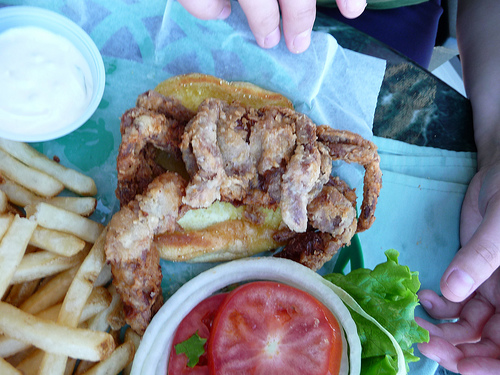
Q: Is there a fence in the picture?
A: No, there are no fences.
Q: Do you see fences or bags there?
A: No, there are no fences or bags.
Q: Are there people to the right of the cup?
A: Yes, there is a person to the right of the cup.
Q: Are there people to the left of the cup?
A: No, the person is to the right of the cup.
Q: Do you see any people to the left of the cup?
A: No, the person is to the right of the cup.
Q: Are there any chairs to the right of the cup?
A: No, there is a person to the right of the cup.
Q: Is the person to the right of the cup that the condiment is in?
A: Yes, the person is to the right of the cup.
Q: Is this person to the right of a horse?
A: No, the person is to the right of the cup.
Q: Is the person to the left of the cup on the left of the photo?
A: No, the person is to the right of the cup.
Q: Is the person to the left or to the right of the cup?
A: The person is to the right of the cup.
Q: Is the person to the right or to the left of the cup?
A: The person is to the right of the cup.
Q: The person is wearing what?
A: The person is wearing trousers.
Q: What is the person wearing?
A: The person is wearing trousers.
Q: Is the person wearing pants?
A: Yes, the person is wearing pants.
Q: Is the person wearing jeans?
A: No, the person is wearing pants.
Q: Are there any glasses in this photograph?
A: No, there are no glasses.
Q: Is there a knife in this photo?
A: No, there are no knives.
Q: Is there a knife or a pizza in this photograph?
A: No, there are no knives or pizzas.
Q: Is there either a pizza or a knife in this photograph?
A: No, there are no knives or pizzas.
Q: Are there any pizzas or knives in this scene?
A: No, there are no knives or pizzas.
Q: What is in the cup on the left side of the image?
A: The condiment is in the cup.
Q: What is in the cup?
A: The condiment is in the cup.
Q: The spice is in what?
A: The spice is in the cup.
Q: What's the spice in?
A: The spice is in the cup.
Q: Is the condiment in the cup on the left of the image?
A: Yes, the condiment is in the cup.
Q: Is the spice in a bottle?
A: No, the spice is in the cup.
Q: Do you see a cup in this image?
A: Yes, there is a cup.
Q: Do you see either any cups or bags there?
A: Yes, there is a cup.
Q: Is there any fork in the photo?
A: No, there are no forks.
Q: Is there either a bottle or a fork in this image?
A: No, there are no forks or bottles.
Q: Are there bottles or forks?
A: No, there are no forks or bottles.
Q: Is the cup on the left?
A: Yes, the cup is on the left of the image.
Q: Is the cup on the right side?
A: No, the cup is on the left of the image.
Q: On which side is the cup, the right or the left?
A: The cup is on the left of the image.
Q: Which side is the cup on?
A: The cup is on the left of the image.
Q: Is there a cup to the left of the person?
A: Yes, there is a cup to the left of the person.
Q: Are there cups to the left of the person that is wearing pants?
A: Yes, there is a cup to the left of the person.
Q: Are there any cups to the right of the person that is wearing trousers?
A: No, the cup is to the left of the person.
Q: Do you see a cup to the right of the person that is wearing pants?
A: No, the cup is to the left of the person.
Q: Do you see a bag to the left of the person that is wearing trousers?
A: No, there is a cup to the left of the person.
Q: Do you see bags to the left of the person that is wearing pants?
A: No, there is a cup to the left of the person.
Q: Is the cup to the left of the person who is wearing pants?
A: Yes, the cup is to the left of the person.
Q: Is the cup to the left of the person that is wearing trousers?
A: Yes, the cup is to the left of the person.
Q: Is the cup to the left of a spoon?
A: No, the cup is to the left of the person.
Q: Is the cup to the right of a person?
A: No, the cup is to the left of a person.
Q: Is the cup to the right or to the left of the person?
A: The cup is to the left of the person.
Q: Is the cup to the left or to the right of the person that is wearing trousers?
A: The cup is to the left of the person.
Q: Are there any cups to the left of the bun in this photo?
A: Yes, there is a cup to the left of the bun.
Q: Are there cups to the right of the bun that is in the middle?
A: No, the cup is to the left of the bun.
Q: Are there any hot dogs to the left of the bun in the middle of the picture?
A: No, there is a cup to the left of the bun.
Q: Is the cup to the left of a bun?
A: Yes, the cup is to the left of a bun.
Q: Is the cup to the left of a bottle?
A: No, the cup is to the left of a bun.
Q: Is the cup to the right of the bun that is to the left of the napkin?
A: No, the cup is to the left of the bun.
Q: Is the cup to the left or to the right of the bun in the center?
A: The cup is to the left of the bun.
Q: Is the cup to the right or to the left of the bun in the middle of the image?
A: The cup is to the left of the bun.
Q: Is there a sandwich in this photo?
A: Yes, there is a sandwich.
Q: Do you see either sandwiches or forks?
A: Yes, there is a sandwich.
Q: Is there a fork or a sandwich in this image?
A: Yes, there is a sandwich.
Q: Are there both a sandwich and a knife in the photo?
A: No, there is a sandwich but no knives.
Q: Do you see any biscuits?
A: No, there are no biscuits.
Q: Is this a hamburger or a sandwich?
A: This is a sandwich.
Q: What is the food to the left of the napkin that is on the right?
A: The food is a sandwich.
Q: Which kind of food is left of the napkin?
A: The food is a sandwich.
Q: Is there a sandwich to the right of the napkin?
A: No, the sandwich is to the left of the napkin.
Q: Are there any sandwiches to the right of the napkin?
A: No, the sandwich is to the left of the napkin.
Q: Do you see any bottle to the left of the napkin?
A: No, there is a sandwich to the left of the napkin.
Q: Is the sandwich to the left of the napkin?
A: Yes, the sandwich is to the left of the napkin.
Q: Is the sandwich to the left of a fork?
A: No, the sandwich is to the left of the napkin.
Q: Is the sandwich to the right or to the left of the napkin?
A: The sandwich is to the left of the napkin.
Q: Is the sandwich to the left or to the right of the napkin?
A: The sandwich is to the left of the napkin.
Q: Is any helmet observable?
A: No, there are no helmets.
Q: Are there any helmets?
A: No, there are no helmets.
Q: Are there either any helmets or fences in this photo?
A: No, there are no helmets or fences.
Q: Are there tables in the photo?
A: Yes, there is a table.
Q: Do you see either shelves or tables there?
A: Yes, there is a table.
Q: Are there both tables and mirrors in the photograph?
A: No, there is a table but no mirrors.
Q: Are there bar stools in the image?
A: No, there are no bar stools.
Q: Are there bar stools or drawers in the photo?
A: No, there are no bar stools or drawers.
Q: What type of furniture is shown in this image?
A: The furniture is a table.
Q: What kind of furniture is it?
A: The piece of furniture is a table.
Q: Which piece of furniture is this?
A: This is a table.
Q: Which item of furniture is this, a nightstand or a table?
A: This is a table.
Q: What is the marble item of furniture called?
A: The piece of furniture is a table.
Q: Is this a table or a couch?
A: This is a table.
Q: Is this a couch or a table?
A: This is a table.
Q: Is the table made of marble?
A: Yes, the table is made of marble.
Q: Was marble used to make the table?
A: Yes, the table is made of marble.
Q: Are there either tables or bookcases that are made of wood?
A: No, there is a table but it is made of marble.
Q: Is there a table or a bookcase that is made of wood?
A: No, there is a table but it is made of marble.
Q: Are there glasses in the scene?
A: No, there are no glasses.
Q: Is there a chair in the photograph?
A: No, there are no chairs.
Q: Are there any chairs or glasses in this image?
A: No, there are no chairs or glasses.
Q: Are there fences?
A: No, there are no fences.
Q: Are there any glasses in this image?
A: No, there are no glasses.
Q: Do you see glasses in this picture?
A: No, there are no glasses.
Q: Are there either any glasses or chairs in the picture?
A: No, there are no glasses or chairs.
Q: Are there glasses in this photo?
A: No, there are no glasses.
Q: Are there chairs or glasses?
A: No, there are no glasses or chairs.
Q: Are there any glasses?
A: No, there are no glasses.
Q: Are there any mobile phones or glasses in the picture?
A: No, there are no glasses or mobile phones.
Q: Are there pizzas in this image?
A: No, there are no pizzas.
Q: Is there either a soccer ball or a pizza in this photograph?
A: No, there are no pizzas or soccer balls.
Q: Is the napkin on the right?
A: Yes, the napkin is on the right of the image.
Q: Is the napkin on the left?
A: No, the napkin is on the right of the image.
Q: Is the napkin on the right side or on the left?
A: The napkin is on the right of the image.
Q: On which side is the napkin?
A: The napkin is on the right of the image.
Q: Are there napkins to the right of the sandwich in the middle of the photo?
A: Yes, there is a napkin to the right of the sandwich.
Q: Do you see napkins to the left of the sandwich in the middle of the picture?
A: No, the napkin is to the right of the sandwich.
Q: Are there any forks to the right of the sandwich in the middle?
A: No, there is a napkin to the right of the sandwich.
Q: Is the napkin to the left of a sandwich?
A: No, the napkin is to the right of a sandwich.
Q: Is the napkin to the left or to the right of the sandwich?
A: The napkin is to the right of the sandwich.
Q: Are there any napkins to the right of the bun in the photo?
A: Yes, there is a napkin to the right of the bun.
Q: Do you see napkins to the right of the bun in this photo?
A: Yes, there is a napkin to the right of the bun.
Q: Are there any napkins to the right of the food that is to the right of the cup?
A: Yes, there is a napkin to the right of the bun.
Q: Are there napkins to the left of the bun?
A: No, the napkin is to the right of the bun.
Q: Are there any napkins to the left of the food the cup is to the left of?
A: No, the napkin is to the right of the bun.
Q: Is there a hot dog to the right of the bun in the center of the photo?
A: No, there is a napkin to the right of the bun.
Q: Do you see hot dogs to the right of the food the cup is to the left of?
A: No, there is a napkin to the right of the bun.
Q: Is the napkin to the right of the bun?
A: Yes, the napkin is to the right of the bun.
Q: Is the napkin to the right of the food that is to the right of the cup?
A: Yes, the napkin is to the right of the bun.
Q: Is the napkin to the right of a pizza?
A: No, the napkin is to the right of the bun.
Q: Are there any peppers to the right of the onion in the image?
A: No, there is a napkin to the right of the onion.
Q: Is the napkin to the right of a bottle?
A: No, the napkin is to the right of an onion.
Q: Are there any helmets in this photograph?
A: No, there are no helmets.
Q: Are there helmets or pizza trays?
A: No, there are no helmets or pizza trays.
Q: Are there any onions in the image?
A: Yes, there is an onion.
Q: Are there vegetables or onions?
A: Yes, there is an onion.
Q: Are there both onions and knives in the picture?
A: No, there is an onion but no knives.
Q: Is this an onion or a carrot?
A: This is an onion.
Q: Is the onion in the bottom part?
A: Yes, the onion is in the bottom of the image.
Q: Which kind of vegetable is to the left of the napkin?
A: The vegetable is an onion.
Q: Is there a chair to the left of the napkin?
A: No, there is an onion to the left of the napkin.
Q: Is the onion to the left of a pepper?
A: No, the onion is to the left of the napkin.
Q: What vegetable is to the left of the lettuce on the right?
A: The vegetable is an onion.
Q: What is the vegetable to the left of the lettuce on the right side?
A: The vegetable is an onion.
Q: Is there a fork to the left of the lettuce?
A: No, there is an onion to the left of the lettuce.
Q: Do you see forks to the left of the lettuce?
A: No, there is an onion to the left of the lettuce.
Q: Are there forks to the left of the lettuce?
A: No, there is an onion to the left of the lettuce.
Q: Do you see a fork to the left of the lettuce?
A: No, there is an onion to the left of the lettuce.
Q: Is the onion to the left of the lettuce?
A: Yes, the onion is to the left of the lettuce.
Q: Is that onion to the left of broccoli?
A: No, the onion is to the left of the lettuce.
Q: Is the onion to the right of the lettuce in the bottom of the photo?
A: No, the onion is to the left of the lettuce.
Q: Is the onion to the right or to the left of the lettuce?
A: The onion is to the left of the lettuce.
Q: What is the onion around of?
A: The onion is around the tomato.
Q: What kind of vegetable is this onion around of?
A: The onion is around the tomato.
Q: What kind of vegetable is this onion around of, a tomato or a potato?
A: The onion is around a tomato.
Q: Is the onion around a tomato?
A: Yes, the onion is around a tomato.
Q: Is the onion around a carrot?
A: No, the onion is around a tomato.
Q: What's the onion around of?
A: The onion is around the tomato.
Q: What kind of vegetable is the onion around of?
A: The onion is around the tomato.